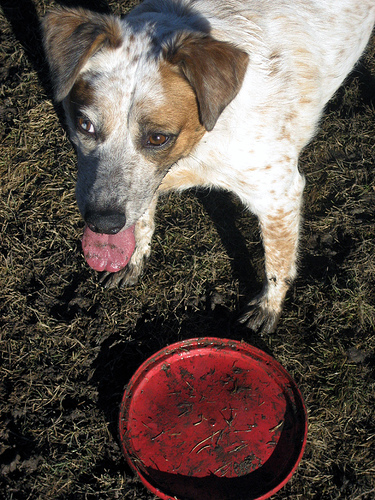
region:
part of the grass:
[289, 365, 305, 378]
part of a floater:
[190, 399, 208, 418]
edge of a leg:
[270, 305, 272, 311]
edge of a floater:
[119, 453, 131, 469]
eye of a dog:
[151, 126, 183, 158]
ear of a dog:
[211, 68, 223, 78]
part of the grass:
[313, 430, 321, 442]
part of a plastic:
[224, 457, 234, 471]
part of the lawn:
[325, 444, 336, 461]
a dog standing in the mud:
[57, 15, 353, 308]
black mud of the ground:
[13, 422, 53, 465]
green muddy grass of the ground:
[309, 348, 363, 412]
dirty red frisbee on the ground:
[107, 346, 314, 494]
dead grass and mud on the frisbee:
[175, 391, 257, 472]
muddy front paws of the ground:
[99, 253, 297, 333]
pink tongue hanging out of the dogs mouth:
[72, 228, 136, 268]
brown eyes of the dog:
[67, 106, 177, 153]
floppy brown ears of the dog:
[23, 4, 238, 126]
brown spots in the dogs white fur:
[262, 31, 321, 148]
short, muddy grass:
[1, 301, 112, 492]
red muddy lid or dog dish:
[118, 338, 307, 497]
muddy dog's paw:
[231, 295, 314, 343]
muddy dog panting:
[43, 2, 367, 318]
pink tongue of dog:
[77, 235, 138, 273]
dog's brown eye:
[145, 128, 169, 147]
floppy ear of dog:
[176, 26, 247, 131]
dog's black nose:
[87, 210, 127, 235]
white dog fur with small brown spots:
[120, 31, 150, 72]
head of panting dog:
[39, 7, 249, 268]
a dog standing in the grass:
[28, 2, 325, 315]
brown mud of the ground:
[34, 338, 76, 387]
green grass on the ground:
[302, 344, 356, 405]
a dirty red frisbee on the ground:
[112, 345, 300, 469]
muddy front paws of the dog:
[94, 266, 288, 330]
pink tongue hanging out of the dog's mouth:
[85, 224, 138, 273]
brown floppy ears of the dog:
[43, 3, 242, 122]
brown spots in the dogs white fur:
[248, 15, 346, 135]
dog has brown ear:
[38, 0, 122, 101]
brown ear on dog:
[162, 30, 249, 130]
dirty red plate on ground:
[117, 338, 306, 498]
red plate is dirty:
[118, 338, 308, 497]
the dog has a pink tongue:
[80, 226, 134, 270]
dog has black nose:
[84, 204, 126, 234]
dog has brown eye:
[150, 131, 166, 145]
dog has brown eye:
[76, 111, 91, 132]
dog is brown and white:
[41, 79, 352, 334]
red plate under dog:
[120, 338, 304, 498]